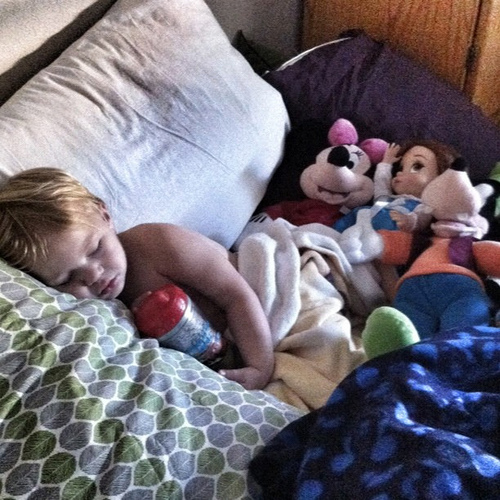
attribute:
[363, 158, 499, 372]
animal — goofy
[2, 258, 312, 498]
design — leaves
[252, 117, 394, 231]
disney character — stuffed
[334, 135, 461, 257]
disney character — stuffed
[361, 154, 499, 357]
disney character — stuffed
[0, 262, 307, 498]
pillow — patterned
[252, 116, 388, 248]
toy — stuffed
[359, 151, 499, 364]
goofy — stuffed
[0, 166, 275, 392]
child — pictured, sleeping, resting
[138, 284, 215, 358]
bottle — pictured, red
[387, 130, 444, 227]
doll — pictured, stuffed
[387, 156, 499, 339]
doll — stuffed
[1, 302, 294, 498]
pillow case — polka dotted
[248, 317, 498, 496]
blanket — blue, black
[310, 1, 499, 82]
cabinet — wooden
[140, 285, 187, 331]
lid — red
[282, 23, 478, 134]
pillow — purple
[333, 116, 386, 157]
bow — pink